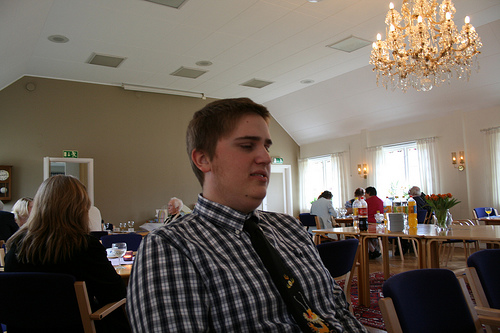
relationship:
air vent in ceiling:
[169, 63, 204, 81] [2, 2, 336, 94]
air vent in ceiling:
[84, 50, 127, 71] [2, 2, 336, 94]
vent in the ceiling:
[89, 41, 119, 75] [167, 10, 246, 36]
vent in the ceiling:
[87, 52, 123, 69] [239, 12, 270, 45]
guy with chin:
[126, 98, 359, 332] [228, 177, 272, 212]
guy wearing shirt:
[126, 98, 359, 332] [184, 242, 259, 322]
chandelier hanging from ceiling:
[376, 3, 475, 86] [310, 2, 349, 29]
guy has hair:
[123, 78, 369, 331] [200, 121, 220, 142]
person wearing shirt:
[363, 180, 376, 211] [374, 195, 378, 210]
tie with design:
[246, 215, 342, 330] [290, 296, 326, 331]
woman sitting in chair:
[9, 180, 97, 300] [67, 281, 100, 321]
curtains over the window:
[386, 141, 429, 182] [366, 126, 437, 190]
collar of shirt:
[202, 204, 225, 219] [204, 245, 235, 303]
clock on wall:
[2, 132, 19, 223] [22, 135, 38, 192]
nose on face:
[254, 149, 280, 169] [230, 114, 284, 197]